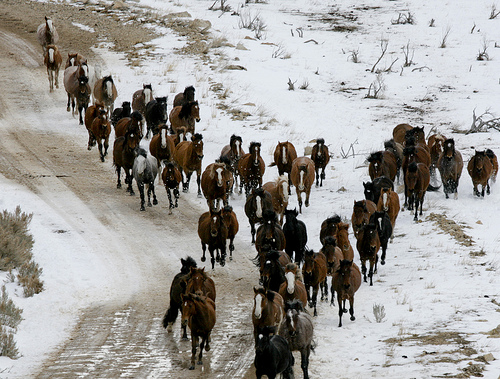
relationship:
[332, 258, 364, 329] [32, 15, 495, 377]
horse in herd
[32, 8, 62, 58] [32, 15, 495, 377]
horse in herd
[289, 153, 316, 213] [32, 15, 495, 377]
horse in herd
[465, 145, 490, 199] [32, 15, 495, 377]
horse in herd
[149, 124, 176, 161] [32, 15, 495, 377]
horse in herd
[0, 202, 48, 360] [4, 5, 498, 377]
bushes in snow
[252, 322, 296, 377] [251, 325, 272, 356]
horse has face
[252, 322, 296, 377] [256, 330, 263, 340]
horse has spot